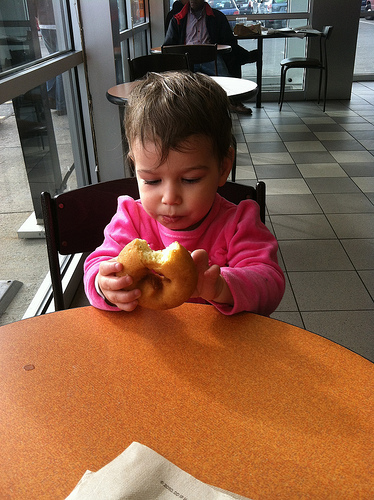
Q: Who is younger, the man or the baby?
A: The baby is younger than the man.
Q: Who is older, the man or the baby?
A: The man is older than the baby.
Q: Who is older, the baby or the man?
A: The man is older than the baby.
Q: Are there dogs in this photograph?
A: No, there are no dogs.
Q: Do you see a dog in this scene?
A: No, there are no dogs.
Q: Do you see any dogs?
A: No, there are no dogs.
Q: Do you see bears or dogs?
A: No, there are no dogs or bears.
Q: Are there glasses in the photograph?
A: No, there are no glasses.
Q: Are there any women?
A: No, there are no women.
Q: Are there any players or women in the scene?
A: No, there are no women or players.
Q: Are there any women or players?
A: No, there are no women or players.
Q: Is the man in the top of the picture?
A: Yes, the man is in the top of the image.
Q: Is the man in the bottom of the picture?
A: No, the man is in the top of the image.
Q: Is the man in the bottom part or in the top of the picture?
A: The man is in the top of the image.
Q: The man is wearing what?
A: The man is wearing a shirt.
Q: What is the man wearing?
A: The man is wearing a shirt.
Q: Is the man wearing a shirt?
A: Yes, the man is wearing a shirt.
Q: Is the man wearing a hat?
A: No, the man is wearing a shirt.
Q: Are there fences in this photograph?
A: No, there are no fences.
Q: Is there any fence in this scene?
A: No, there are no fences.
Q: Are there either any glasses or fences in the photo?
A: No, there are no fences or glasses.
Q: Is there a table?
A: Yes, there is a table.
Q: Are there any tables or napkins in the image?
A: Yes, there is a table.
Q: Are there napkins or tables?
A: Yes, there is a table.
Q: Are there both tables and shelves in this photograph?
A: No, there is a table but no shelves.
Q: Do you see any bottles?
A: No, there are no bottles.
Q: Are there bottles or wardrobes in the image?
A: No, there are no bottles or wardrobes.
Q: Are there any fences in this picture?
A: No, there are no fences.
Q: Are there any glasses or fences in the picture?
A: No, there are no fences or glasses.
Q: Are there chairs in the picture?
A: Yes, there is a chair.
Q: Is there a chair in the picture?
A: Yes, there is a chair.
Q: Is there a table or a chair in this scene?
A: Yes, there is a chair.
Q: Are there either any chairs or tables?
A: Yes, there is a chair.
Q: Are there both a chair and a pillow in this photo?
A: No, there is a chair but no pillows.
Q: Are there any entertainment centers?
A: No, there are no entertainment centers.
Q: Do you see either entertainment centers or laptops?
A: No, there are no entertainment centers or laptops.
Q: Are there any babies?
A: Yes, there is a baby.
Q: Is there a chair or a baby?
A: Yes, there is a baby.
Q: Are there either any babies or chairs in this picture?
A: Yes, there is a baby.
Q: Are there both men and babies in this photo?
A: Yes, there are both a baby and a man.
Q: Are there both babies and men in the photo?
A: Yes, there are both a baby and a man.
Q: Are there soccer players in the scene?
A: No, there are no soccer players.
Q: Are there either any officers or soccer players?
A: No, there are no soccer players or officers.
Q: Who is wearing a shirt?
A: The baby is wearing a shirt.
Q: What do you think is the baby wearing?
A: The baby is wearing a shirt.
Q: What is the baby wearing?
A: The baby is wearing a shirt.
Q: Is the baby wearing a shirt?
A: Yes, the baby is wearing a shirt.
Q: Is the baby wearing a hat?
A: No, the baby is wearing a shirt.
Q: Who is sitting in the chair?
A: The baby is sitting in the chair.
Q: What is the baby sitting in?
A: The baby is sitting in the chair.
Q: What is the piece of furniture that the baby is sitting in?
A: The piece of furniture is a chair.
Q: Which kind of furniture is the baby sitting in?
A: The baby is sitting in the chair.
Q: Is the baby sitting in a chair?
A: Yes, the baby is sitting in a chair.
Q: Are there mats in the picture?
A: No, there are no mats.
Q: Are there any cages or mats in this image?
A: No, there are no mats or cages.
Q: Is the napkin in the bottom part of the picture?
A: Yes, the napkin is in the bottom of the image.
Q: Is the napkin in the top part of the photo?
A: No, the napkin is in the bottom of the image.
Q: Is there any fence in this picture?
A: No, there are no fences.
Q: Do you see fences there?
A: No, there are no fences.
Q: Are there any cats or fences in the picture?
A: No, there are no fences or cats.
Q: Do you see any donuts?
A: Yes, there is a donut.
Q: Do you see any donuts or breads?
A: Yes, there is a donut.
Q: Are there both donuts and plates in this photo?
A: No, there is a donut but no plates.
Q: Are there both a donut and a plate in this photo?
A: No, there is a donut but no plates.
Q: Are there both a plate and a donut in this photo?
A: No, there is a donut but no plates.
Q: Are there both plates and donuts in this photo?
A: No, there is a donut but no plates.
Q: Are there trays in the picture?
A: No, there are no trays.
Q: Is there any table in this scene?
A: Yes, there is a table.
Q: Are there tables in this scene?
A: Yes, there is a table.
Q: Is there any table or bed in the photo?
A: Yes, there is a table.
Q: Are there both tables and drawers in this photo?
A: No, there is a table but no drawers.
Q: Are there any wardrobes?
A: No, there are no wardrobes.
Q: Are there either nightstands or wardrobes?
A: No, there are no wardrobes or nightstands.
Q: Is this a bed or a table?
A: This is a table.